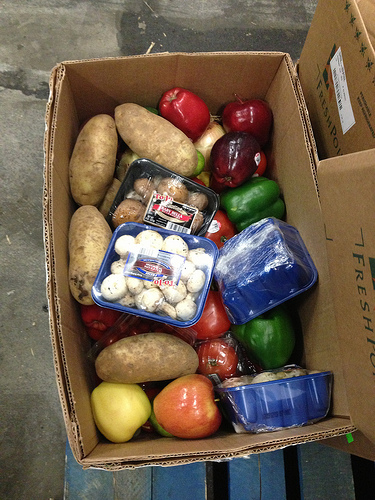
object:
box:
[42, 50, 358, 476]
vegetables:
[66, 202, 115, 307]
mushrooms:
[101, 269, 127, 303]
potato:
[115, 103, 198, 178]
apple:
[158, 87, 211, 142]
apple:
[90, 383, 151, 444]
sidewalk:
[3, 4, 374, 496]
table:
[60, 434, 357, 498]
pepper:
[218, 178, 287, 231]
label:
[131, 256, 176, 287]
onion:
[192, 120, 225, 171]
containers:
[91, 220, 219, 328]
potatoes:
[68, 113, 118, 205]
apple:
[212, 128, 261, 188]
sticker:
[254, 151, 262, 166]